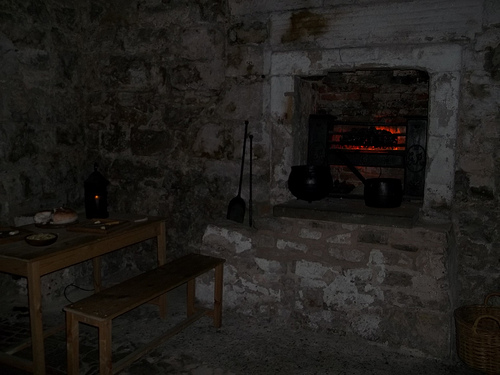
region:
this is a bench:
[52, 242, 239, 353]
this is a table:
[15, 159, 185, 353]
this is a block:
[295, 241, 385, 342]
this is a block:
[378, 252, 452, 366]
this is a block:
[195, 219, 287, 321]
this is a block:
[157, 63, 255, 168]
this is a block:
[78, 39, 133, 134]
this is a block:
[177, 46, 232, 131]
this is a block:
[438, 25, 489, 150]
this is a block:
[284, 8, 365, 73]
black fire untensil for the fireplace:
[218, 114, 255, 228]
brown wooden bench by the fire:
[56, 245, 236, 374]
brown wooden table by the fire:
[0, 202, 172, 373]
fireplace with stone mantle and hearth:
[192, 38, 475, 345]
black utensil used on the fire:
[243, 128, 257, 230]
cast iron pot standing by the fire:
[283, 158, 336, 207]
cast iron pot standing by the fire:
[343, 157, 400, 214]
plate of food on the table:
[32, 206, 82, 227]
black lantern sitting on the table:
[81, 163, 110, 223]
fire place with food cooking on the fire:
[189, 28, 476, 358]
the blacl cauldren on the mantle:
[285, 159, 329, 204]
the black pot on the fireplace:
[346, 161, 408, 211]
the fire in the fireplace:
[330, 121, 397, 148]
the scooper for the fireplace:
[225, 115, 255, 230]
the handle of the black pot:
[343, 158, 365, 185]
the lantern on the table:
[80, 159, 110, 215]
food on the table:
[14, 194, 79, 256]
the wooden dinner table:
[0, 211, 165, 271]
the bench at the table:
[65, 252, 226, 364]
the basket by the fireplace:
[453, 296, 498, 373]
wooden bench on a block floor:
[57, 246, 232, 373]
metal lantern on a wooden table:
[75, 154, 117, 232]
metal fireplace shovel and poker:
[218, 113, 264, 237]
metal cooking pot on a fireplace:
[333, 149, 418, 224]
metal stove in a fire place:
[306, 101, 428, 171]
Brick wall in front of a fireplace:
[293, 249, 398, 310]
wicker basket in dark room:
[449, 287, 499, 373]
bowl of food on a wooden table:
[18, 224, 71, 256]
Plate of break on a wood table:
[21, 197, 83, 235]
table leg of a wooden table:
[19, 275, 59, 373]